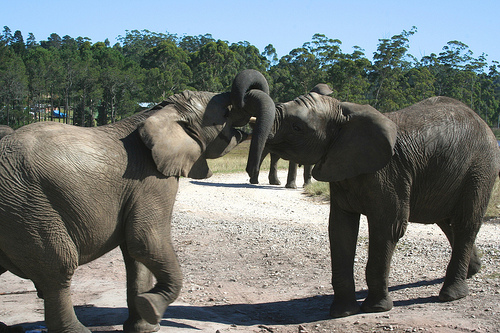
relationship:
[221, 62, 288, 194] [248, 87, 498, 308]
trunks coiled with elephant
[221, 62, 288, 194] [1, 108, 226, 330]
trunks coiled with elephant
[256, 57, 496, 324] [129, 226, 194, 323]
elephant lifting leg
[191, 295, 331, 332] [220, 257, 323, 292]
elephant shadow on ground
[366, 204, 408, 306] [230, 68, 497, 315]
front leg on elephant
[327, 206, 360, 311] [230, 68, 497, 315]
front leg on elephant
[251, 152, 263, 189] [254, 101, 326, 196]
leg on elephant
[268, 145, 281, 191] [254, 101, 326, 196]
leg on elephant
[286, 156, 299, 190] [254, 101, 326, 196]
leg on elephant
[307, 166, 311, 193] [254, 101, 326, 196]
leg on elephant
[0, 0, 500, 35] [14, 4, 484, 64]
cloud in sky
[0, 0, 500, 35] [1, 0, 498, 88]
cloud in blue sky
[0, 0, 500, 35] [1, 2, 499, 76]
cloud in sky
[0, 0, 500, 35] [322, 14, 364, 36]
cloud in sky